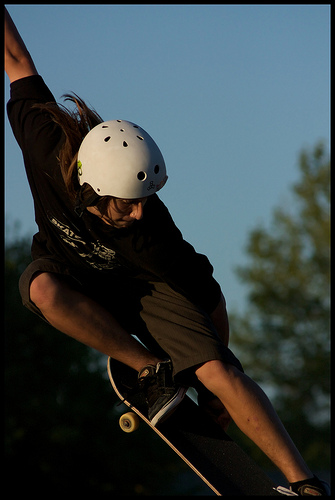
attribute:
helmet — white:
[72, 107, 171, 202]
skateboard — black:
[114, 356, 264, 498]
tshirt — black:
[12, 80, 155, 266]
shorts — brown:
[14, 241, 251, 372]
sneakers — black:
[133, 368, 325, 496]